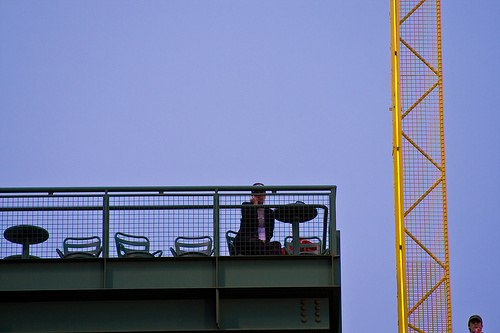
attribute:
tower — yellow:
[388, 1, 451, 332]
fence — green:
[0, 185, 337, 260]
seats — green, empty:
[56, 229, 328, 259]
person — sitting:
[231, 182, 282, 254]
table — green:
[3, 225, 48, 257]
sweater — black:
[232, 203, 275, 254]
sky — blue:
[0, 0, 499, 332]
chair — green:
[170, 236, 215, 256]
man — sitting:
[469, 314, 485, 332]